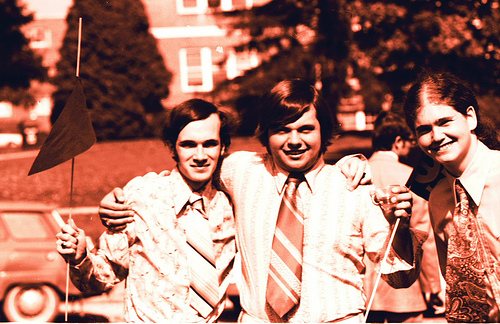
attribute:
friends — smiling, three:
[53, 77, 499, 317]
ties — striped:
[258, 174, 316, 321]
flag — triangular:
[49, 37, 100, 319]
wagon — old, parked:
[2, 195, 126, 315]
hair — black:
[161, 106, 210, 130]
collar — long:
[153, 170, 194, 215]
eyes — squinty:
[176, 125, 223, 154]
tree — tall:
[53, 0, 166, 137]